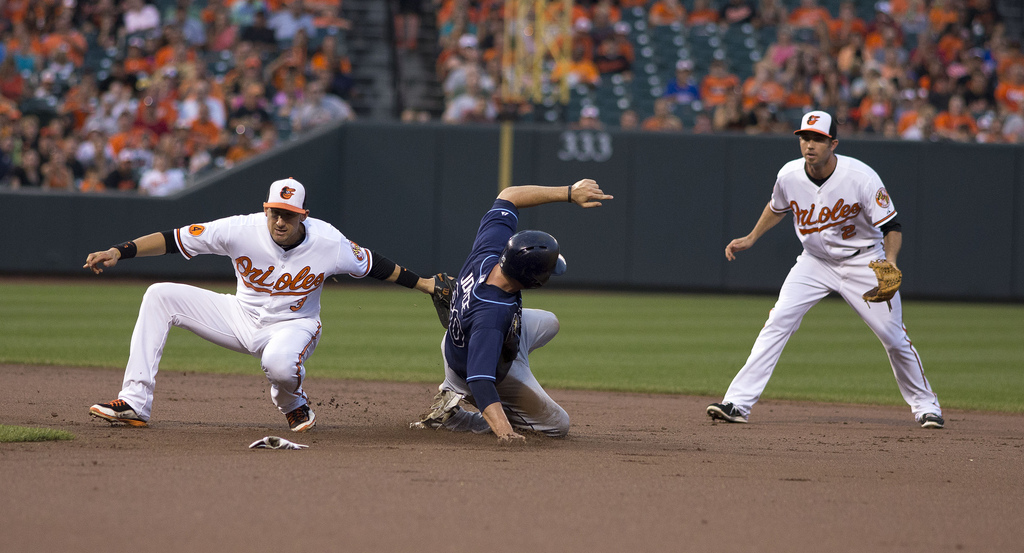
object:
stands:
[0, 0, 1024, 199]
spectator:
[933, 93, 977, 134]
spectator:
[76, 128, 119, 168]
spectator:
[443, 67, 492, 104]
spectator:
[701, 62, 740, 106]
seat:
[607, 98, 643, 115]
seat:
[737, 50, 765, 64]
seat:
[633, 75, 666, 87]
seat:
[636, 46, 663, 62]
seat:
[657, 23, 685, 37]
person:
[288, 80, 356, 130]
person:
[139, 153, 186, 198]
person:
[102, 156, 141, 189]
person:
[83, 92, 124, 134]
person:
[662, 59, 700, 100]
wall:
[0, 115, 1024, 303]